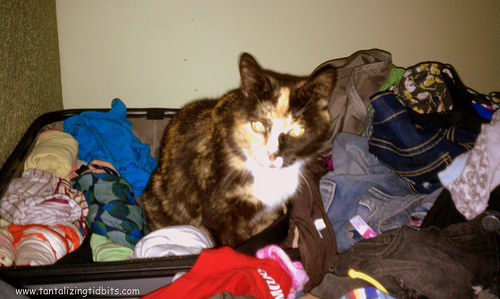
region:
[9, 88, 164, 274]
rolled up clothing in suitcase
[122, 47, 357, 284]
brown and orange cat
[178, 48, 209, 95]
brown stains on wall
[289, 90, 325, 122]
white whiskers above cat eye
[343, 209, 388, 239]
small tag on clothing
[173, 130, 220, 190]
fur on side of cat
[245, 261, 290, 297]
white text on red shirt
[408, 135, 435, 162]
yellow stitching on clothing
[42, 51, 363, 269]
cat sitting in suitcase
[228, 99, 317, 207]
camera flash on cat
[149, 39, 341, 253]
a brown cat sitting in a suitcase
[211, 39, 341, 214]
a white spot on the cat's chest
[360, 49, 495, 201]
a dark colored pair of jeans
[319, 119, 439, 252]
a light colored pair of jeans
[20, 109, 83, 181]
a piece of yellow clothing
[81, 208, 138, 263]
a piece of green clothing rolled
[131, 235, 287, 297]
a red shirt in front of the cat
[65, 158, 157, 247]
a blue and green piece of clothing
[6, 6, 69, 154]
a gold colored wall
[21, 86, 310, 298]
a suitcase full of clothing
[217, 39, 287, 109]
ear of the cat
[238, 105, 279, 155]
eye of the cat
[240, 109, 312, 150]
eyes of the cat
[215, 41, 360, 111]
two ears of the cat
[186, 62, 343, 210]
white, brown and black cat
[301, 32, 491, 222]
clothing next to the cat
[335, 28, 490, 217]
clothes on the bed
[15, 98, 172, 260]
clothing in the suitcase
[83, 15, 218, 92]
wall behind the cat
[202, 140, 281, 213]
whiskers on cat's face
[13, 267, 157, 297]
website in bottom left corner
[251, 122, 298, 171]
nose of the cat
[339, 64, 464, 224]
clothing next to cat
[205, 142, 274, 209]
whiskers on the cat's face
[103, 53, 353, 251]
cat in a suitcase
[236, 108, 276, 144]
eye of the cat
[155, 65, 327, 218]
black and brown and white cat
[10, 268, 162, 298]
website in bottom left corner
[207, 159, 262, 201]
whiskers on the cat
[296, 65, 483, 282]
clothing on the bed